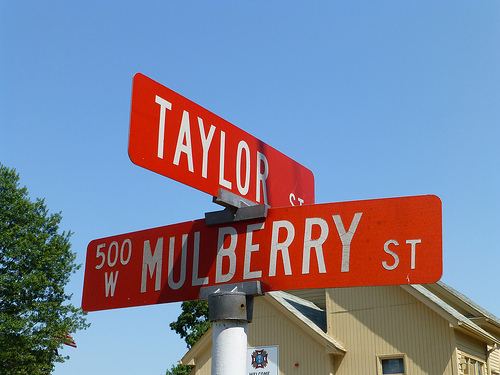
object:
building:
[176, 216, 499, 374]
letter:
[211, 222, 241, 288]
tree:
[0, 157, 88, 375]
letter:
[238, 219, 267, 280]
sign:
[79, 194, 441, 313]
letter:
[189, 226, 211, 288]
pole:
[204, 181, 272, 373]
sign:
[126, 72, 330, 226]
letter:
[139, 237, 166, 293]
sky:
[0, 1, 499, 373]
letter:
[167, 233, 191, 294]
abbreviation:
[378, 234, 424, 272]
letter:
[145, 94, 173, 168]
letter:
[173, 107, 195, 172]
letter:
[195, 114, 215, 181]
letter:
[216, 128, 231, 189]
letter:
[378, 234, 400, 271]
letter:
[403, 233, 422, 269]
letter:
[254, 147, 271, 208]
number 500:
[88, 238, 134, 269]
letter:
[266, 218, 296, 278]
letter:
[327, 210, 370, 273]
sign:
[294, 216, 334, 279]